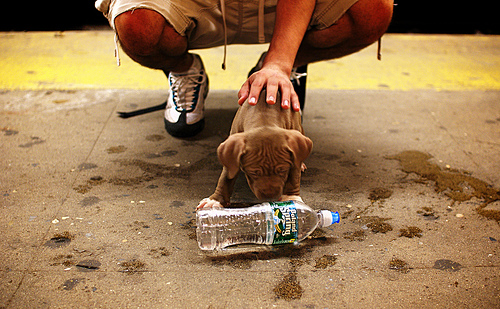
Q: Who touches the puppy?
A: A man.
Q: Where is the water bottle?
A: On the ground.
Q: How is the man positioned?
A: He is crouching.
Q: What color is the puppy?
A: Brown.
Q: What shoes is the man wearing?
A: Sneakers.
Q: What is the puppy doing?
A: Sniffing the bottle.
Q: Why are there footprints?
A: The puppy tracked water.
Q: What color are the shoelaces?
A: White.